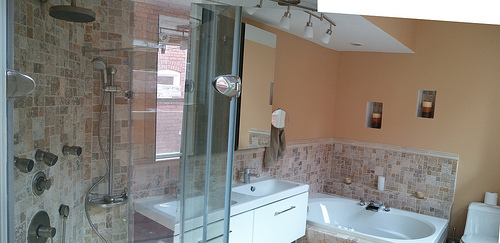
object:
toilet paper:
[481, 191, 499, 205]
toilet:
[461, 200, 500, 243]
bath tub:
[303, 199, 448, 242]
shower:
[1, 1, 239, 242]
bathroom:
[4, 0, 499, 242]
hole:
[364, 101, 382, 129]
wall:
[244, 24, 499, 225]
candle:
[418, 101, 431, 117]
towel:
[262, 123, 290, 169]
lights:
[317, 28, 335, 45]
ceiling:
[247, 0, 498, 57]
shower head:
[90, 56, 109, 84]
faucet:
[237, 167, 260, 184]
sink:
[233, 181, 300, 197]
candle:
[371, 112, 380, 128]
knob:
[34, 174, 55, 193]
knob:
[13, 156, 36, 172]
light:
[276, 11, 292, 29]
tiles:
[330, 143, 458, 219]